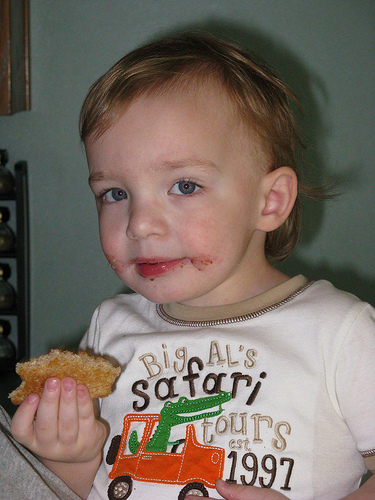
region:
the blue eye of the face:
[102, 187, 125, 202]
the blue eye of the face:
[169, 179, 203, 195]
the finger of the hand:
[11, 395, 39, 443]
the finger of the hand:
[39, 377, 58, 439]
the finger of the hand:
[58, 375, 78, 439]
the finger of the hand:
[77, 383, 94, 436]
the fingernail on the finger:
[46, 379, 58, 390]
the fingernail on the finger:
[28, 394, 37, 404]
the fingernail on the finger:
[64, 379, 72, 390]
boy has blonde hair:
[149, 49, 173, 70]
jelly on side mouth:
[193, 258, 214, 272]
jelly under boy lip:
[134, 272, 158, 282]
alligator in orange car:
[157, 394, 236, 445]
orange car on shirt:
[187, 455, 198, 469]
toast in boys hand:
[17, 345, 119, 420]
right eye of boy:
[157, 158, 218, 221]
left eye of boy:
[80, 166, 136, 218]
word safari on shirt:
[130, 360, 270, 403]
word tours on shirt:
[200, 408, 292, 441]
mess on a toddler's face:
[187, 252, 213, 274]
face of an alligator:
[159, 385, 236, 428]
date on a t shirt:
[226, 438, 295, 495]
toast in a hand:
[8, 343, 122, 429]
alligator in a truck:
[103, 388, 243, 496]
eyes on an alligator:
[160, 393, 188, 409]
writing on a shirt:
[131, 337, 268, 407]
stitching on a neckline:
[239, 307, 259, 322]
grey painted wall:
[46, 238, 69, 276]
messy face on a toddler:
[109, 243, 212, 291]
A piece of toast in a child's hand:
[9, 344, 123, 401]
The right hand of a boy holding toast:
[6, 376, 112, 462]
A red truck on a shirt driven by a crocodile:
[104, 411, 226, 498]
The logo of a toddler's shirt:
[105, 337, 297, 498]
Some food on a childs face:
[191, 252, 216, 270]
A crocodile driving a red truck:
[127, 391, 232, 454]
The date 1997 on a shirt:
[224, 451, 294, 490]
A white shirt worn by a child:
[79, 278, 372, 499]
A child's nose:
[125, 207, 168, 240]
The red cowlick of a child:
[212, 44, 310, 116]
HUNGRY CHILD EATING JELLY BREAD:
[6, 16, 361, 499]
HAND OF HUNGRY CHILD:
[3, 370, 113, 481]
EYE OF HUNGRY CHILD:
[88, 182, 132, 207]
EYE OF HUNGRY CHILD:
[162, 175, 211, 201]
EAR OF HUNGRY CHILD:
[252, 159, 302, 237]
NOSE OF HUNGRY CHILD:
[118, 190, 172, 245]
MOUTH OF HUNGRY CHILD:
[124, 250, 199, 278]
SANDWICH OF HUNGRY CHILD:
[10, 348, 127, 399]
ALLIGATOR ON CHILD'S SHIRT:
[104, 387, 228, 453]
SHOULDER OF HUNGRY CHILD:
[85, 295, 153, 342]